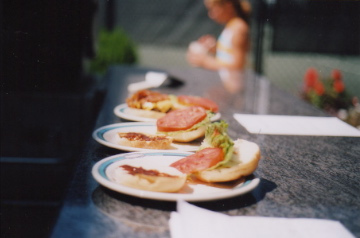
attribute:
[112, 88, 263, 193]
food — meatless, boring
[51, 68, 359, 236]
counter — gray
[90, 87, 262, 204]
plates — white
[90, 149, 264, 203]
first plate — blue, white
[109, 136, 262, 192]
burger — open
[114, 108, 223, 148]
burger — open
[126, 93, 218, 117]
burger — open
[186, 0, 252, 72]
kid — standing, walking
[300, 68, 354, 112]
flowers — orange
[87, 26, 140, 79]
bush — small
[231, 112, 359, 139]
paper — white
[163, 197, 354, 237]
paper — white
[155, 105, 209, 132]
tomato — red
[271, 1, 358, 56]
background — black